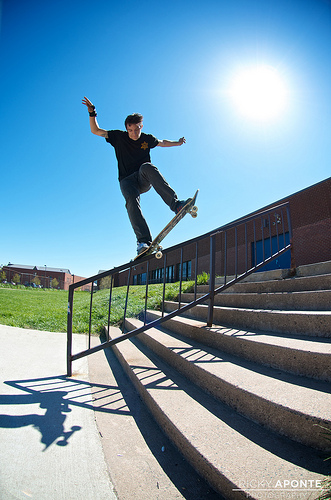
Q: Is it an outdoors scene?
A: Yes, it is outdoors.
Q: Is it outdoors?
A: Yes, it is outdoors.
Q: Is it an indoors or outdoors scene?
A: It is outdoors.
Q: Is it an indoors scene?
A: No, it is outdoors.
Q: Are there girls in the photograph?
A: No, there are no girls.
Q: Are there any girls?
A: No, there are no girls.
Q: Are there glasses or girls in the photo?
A: No, there are no girls or glasses.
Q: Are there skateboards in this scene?
A: Yes, there is a skateboard.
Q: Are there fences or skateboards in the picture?
A: Yes, there is a skateboard.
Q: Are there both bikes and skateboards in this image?
A: No, there is a skateboard but no bikes.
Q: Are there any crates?
A: No, there are no crates.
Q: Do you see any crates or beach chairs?
A: No, there are no crates or beach chairs.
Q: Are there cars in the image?
A: No, there are no cars.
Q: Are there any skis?
A: No, there are no skis.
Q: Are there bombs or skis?
A: No, there are no skis or bombs.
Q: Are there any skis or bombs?
A: No, there are no skis or bombs.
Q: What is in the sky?
A: The sun is in the sky.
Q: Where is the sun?
A: The sun is in the sky.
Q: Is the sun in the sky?
A: Yes, the sun is in the sky.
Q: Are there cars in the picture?
A: No, there are no cars.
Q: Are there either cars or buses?
A: No, there are no cars or buses.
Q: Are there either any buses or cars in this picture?
A: No, there are no cars or buses.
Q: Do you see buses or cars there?
A: No, there are no cars or buses.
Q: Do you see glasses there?
A: No, there are no glasses.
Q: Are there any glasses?
A: No, there are no glasses.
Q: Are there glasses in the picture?
A: No, there are no glasses.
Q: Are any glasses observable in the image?
A: No, there are no glasses.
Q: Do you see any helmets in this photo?
A: No, there are no helmets.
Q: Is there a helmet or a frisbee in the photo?
A: No, there are no helmets or frisbees.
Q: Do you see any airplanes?
A: No, there are no airplanes.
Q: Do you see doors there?
A: Yes, there are doors.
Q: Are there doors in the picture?
A: Yes, there are doors.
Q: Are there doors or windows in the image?
A: Yes, there are doors.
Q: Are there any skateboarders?
A: Yes, there is a skateboarder.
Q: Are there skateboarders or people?
A: Yes, there is a skateboarder.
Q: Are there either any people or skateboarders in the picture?
A: Yes, there is a skateboarder.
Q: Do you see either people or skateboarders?
A: Yes, there is a skateboarder.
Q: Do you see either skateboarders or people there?
A: Yes, there is a skateboarder.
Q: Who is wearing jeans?
A: The skateboarder is wearing jeans.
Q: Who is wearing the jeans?
A: The skateboarder is wearing jeans.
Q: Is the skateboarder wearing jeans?
A: Yes, the skateboarder is wearing jeans.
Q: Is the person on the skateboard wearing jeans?
A: Yes, the skateboarder is wearing jeans.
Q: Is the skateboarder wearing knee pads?
A: No, the skateboarder is wearing jeans.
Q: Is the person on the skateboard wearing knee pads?
A: No, the skateboarder is wearing jeans.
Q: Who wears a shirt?
A: The skateboarder wears a shirt.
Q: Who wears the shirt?
A: The skateboarder wears a shirt.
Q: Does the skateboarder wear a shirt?
A: Yes, the skateboarder wears a shirt.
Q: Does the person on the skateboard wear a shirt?
A: Yes, the skateboarder wears a shirt.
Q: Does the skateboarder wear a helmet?
A: No, the skateboarder wears a shirt.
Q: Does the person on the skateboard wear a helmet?
A: No, the skateboarder wears a shirt.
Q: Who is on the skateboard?
A: The skateboarder is on the skateboard.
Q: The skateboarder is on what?
A: The skateboarder is on the skateboard.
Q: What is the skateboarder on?
A: The skateboarder is on the skateboard.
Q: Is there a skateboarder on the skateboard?
A: Yes, there is a skateboarder on the skateboard.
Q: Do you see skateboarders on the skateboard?
A: Yes, there is a skateboarder on the skateboard.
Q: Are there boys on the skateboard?
A: No, there is a skateboarder on the skateboard.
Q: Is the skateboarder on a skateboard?
A: Yes, the skateboarder is on a skateboard.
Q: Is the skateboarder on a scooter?
A: No, the skateboarder is on a skateboard.